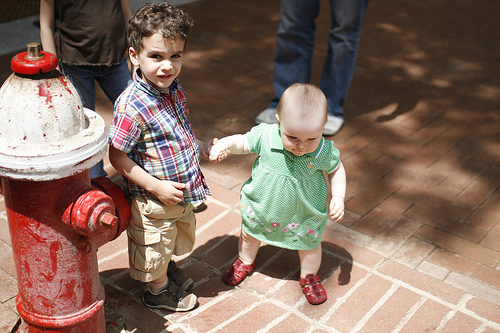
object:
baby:
[207, 82, 347, 306]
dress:
[239, 121, 339, 250]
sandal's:
[299, 273, 328, 304]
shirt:
[107, 74, 212, 207]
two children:
[105, 0, 348, 314]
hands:
[196, 137, 229, 163]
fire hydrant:
[0, 40, 137, 332]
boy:
[108, 2, 212, 314]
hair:
[121, 1, 195, 53]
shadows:
[95, 232, 350, 332]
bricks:
[376, 257, 465, 307]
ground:
[351, 131, 491, 326]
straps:
[168, 281, 184, 300]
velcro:
[166, 290, 175, 297]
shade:
[179, 6, 500, 255]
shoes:
[140, 287, 196, 311]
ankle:
[141, 287, 166, 306]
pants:
[126, 195, 197, 282]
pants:
[265, 0, 364, 116]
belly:
[61, 13, 128, 48]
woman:
[38, 1, 141, 112]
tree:
[458, 4, 499, 26]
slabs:
[355, 190, 415, 241]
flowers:
[270, 221, 280, 244]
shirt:
[52, 0, 134, 68]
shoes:
[323, 111, 340, 136]